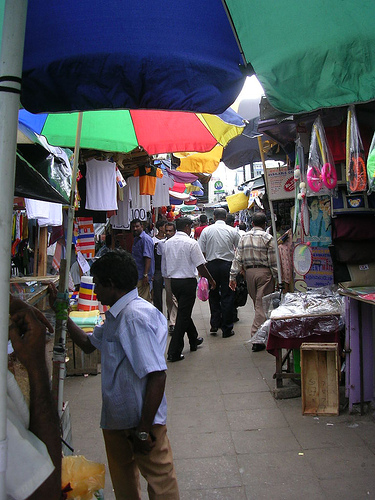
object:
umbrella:
[15, 105, 249, 161]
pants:
[105, 425, 179, 499]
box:
[299, 341, 341, 418]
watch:
[136, 429, 149, 441]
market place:
[0, 0, 375, 499]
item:
[306, 113, 337, 193]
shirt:
[164, 231, 208, 280]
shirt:
[87, 288, 170, 430]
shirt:
[85, 158, 119, 212]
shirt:
[309, 211, 331, 251]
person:
[196, 208, 243, 338]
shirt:
[228, 226, 278, 284]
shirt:
[134, 167, 164, 195]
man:
[228, 211, 283, 352]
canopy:
[221, 98, 286, 170]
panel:
[130, 108, 218, 159]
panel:
[41, 108, 139, 154]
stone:
[226, 409, 288, 431]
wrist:
[136, 422, 152, 436]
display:
[256, 107, 374, 213]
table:
[268, 286, 344, 325]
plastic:
[244, 285, 348, 351]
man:
[41, 251, 185, 499]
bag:
[60, 454, 106, 499]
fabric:
[22, 1, 248, 116]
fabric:
[227, 1, 375, 116]